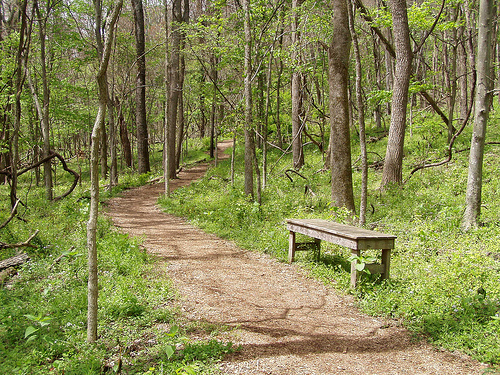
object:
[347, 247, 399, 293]
legs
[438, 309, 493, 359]
grass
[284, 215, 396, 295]
bench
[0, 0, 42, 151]
leaves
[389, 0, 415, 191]
tree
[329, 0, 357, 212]
tree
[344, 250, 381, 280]
weeds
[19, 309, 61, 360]
plant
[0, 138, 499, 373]
ground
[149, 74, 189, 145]
floor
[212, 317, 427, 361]
shadow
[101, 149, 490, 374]
dirt path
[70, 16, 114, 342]
trees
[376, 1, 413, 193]
trunk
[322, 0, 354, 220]
trunk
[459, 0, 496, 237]
trunk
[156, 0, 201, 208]
trunk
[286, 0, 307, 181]
trunk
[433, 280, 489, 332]
grass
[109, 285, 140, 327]
grass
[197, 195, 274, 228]
grass patch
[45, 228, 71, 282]
grass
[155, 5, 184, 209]
tree